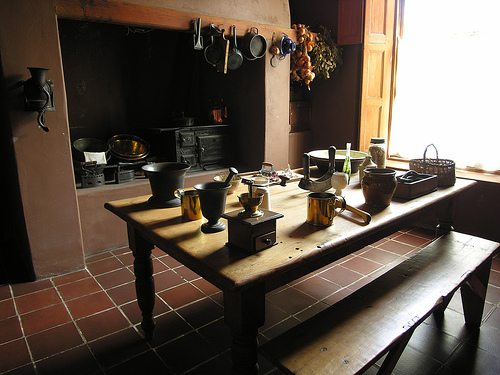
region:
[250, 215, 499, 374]
a bench of wood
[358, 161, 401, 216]
vase on the table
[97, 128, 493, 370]
bench and table are brown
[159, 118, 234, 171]
the old black stove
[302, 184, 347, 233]
a cup on table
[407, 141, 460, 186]
a basket on corner of table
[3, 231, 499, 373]
floor is color red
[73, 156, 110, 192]
the iron is black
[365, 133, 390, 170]
a glass is filled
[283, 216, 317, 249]
a shadow on the table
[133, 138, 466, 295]
table with many cookware items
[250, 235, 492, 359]
bench by the table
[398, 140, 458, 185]
basket with handle on table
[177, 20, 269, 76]
hanging pots and pans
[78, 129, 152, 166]
pots and pans on shelf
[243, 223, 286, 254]
drawer on the container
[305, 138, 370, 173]
bowl on the table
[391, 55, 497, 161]
curtain in the window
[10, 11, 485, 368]
Scene takes place in a kitchen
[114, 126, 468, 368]
Large table in the kitchen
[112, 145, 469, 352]
The table is made of wood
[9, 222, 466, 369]
The flooring is tile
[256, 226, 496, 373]
Long wooden bench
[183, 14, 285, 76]
Pots hanging from the wall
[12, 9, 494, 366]
No people in the photo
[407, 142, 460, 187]
Basket on the table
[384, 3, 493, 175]
Sunlight coming through the window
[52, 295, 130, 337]
tile floor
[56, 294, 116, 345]
the floor is brown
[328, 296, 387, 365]
a bench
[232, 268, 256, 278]
the table is brown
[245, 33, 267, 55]
a black pan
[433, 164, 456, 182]
a basket on the table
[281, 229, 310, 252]
a wooden table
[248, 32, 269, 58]
a pot hanging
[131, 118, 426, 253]
supplies on top of table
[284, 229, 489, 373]
brown wooden bench of table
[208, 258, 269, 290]
brown wooden top of table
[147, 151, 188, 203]
small black bucket o table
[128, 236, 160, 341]
wooden leg of table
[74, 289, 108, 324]
red tile on ground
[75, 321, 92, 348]
white grout of tile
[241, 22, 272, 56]
black pan hanging from wall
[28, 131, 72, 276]
brown walls of room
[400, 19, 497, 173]
large bright window on side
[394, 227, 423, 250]
a tile in a floor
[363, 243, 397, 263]
a tile in a floor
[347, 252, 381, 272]
a tile in a floor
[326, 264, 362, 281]
a tile in a floor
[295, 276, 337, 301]
a tile in a floor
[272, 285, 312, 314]
a tile in a floor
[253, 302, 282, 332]
a tile in a floor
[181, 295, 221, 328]
a tile in a floor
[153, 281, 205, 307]
a tile in a floor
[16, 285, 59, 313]
a tile in a floor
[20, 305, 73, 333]
a tile in a floor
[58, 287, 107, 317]
a tile in a floor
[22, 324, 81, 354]
a tile in a floor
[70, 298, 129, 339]
a tile in a floor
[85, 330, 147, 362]
a tile in a floor